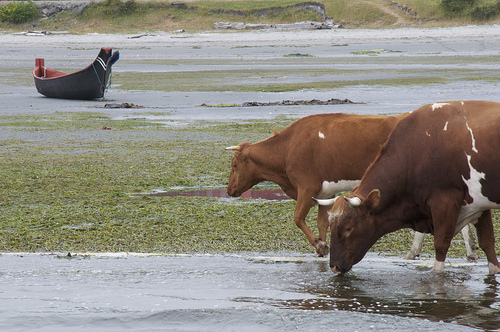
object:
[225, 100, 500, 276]
cows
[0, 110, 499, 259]
grass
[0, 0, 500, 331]
ground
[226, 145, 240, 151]
horn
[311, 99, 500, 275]
cow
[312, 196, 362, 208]
horns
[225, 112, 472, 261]
cow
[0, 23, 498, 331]
water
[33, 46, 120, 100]
boat